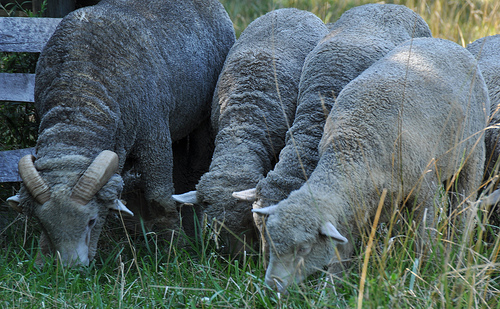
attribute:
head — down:
[7, 157, 132, 277]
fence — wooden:
[3, 16, 60, 186]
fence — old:
[0, 17, 142, 184]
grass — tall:
[366, 255, 497, 302]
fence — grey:
[4, 3, 74, 212]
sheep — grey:
[27, 12, 495, 301]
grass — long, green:
[10, 207, 497, 305]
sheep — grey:
[259, 37, 489, 287]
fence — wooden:
[1, 4, 54, 217]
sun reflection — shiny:
[399, 49, 456, 81]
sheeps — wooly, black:
[8, 0, 498, 276]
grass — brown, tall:
[2, 0, 499, 307]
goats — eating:
[35, 12, 482, 304]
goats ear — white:
[243, 201, 305, 219]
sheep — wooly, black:
[168, 15, 498, 293]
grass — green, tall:
[2, 197, 499, 302]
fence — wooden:
[0, 13, 64, 185]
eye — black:
[77, 212, 102, 231]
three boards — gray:
[0, 11, 51, 192]